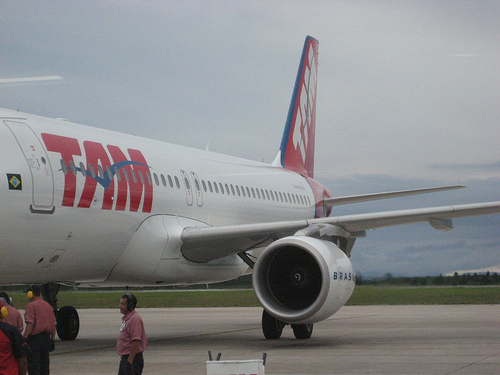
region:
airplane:
[27, 38, 464, 302]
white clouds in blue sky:
[397, 111, 428, 133]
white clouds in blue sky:
[387, 75, 452, 107]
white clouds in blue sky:
[162, 26, 232, 74]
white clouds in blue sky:
[57, 55, 139, 95]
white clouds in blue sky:
[147, 38, 215, 105]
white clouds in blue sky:
[344, 71, 381, 106]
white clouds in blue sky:
[411, 48, 442, 80]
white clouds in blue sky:
[88, 51, 182, 112]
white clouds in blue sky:
[382, 58, 434, 112]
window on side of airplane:
[166, 163, 185, 190]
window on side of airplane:
[147, 170, 172, 191]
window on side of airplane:
[121, 165, 149, 184]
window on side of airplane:
[91, 163, 116, 183]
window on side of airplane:
[73, 159, 94, 182]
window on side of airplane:
[57, 154, 77, 180]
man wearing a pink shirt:
[108, 308, 153, 370]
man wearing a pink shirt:
[23, 295, 56, 349]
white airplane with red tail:
[10, 22, 489, 329]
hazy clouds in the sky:
[343, 155, 499, 171]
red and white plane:
[9, 28, 436, 308]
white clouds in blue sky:
[351, 139, 383, 166]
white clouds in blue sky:
[389, 92, 414, 150]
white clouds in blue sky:
[184, 13, 212, 59]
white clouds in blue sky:
[407, 85, 447, 140]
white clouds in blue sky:
[117, 73, 174, 122]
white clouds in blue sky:
[131, 11, 161, 41]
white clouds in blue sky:
[108, 52, 158, 102]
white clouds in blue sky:
[421, 1, 498, 75]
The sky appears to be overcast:
[0, 0, 496, 180]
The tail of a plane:
[270, 31, 322, 177]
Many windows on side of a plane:
[55, 151, 315, 208]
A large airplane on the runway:
[0, 31, 495, 368]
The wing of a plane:
[176, 195, 496, 322]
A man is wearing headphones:
[111, 287, 137, 314]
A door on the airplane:
[0, 111, 56, 211]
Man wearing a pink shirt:
[20, 280, 60, 335]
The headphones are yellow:
[20, 280, 42, 300]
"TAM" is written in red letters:
[36, 126, 156, 216]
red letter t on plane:
[36, 124, 83, 212]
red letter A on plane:
[79, 137, 115, 210]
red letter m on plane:
[112, 141, 157, 216]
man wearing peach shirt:
[128, 325, 141, 334]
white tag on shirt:
[116, 321, 128, 331]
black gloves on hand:
[123, 358, 131, 373]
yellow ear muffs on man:
[27, 291, 35, 298]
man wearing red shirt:
[2, 336, 11, 366]